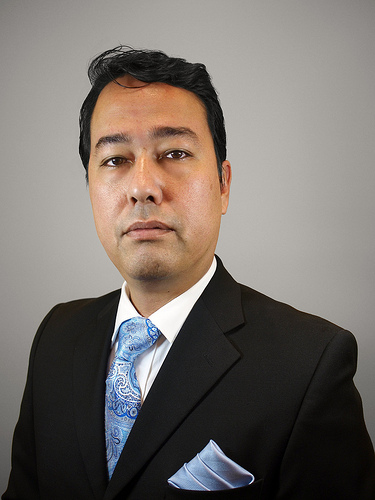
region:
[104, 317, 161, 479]
blue paisley neck tie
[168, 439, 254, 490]
pocket kerchief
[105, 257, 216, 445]
white collared shirt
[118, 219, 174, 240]
his mouth is closed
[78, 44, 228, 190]
He has short black hair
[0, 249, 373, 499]
the man is wearing a black suit jacket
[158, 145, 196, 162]
The man's eye is brown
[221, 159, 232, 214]
this is the man's ear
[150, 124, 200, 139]
The man's eyebrow is black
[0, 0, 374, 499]
the background is grey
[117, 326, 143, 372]
the tie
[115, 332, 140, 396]
the tie is blue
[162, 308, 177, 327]
a collar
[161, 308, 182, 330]
the collar is white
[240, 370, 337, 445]
a black suit the man is wearing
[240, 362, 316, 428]
the suit is black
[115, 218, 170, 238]
the mans lips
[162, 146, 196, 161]
left eye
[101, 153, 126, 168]
right eye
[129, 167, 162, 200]
the mans nose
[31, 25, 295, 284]
a man standing inside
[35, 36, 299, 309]
a man with black hair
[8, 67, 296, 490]
a man wearing a tie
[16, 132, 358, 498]
a man wearing a blue tie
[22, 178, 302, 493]
a man wearing a white shirt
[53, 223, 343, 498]
a man wearing a suit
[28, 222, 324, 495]
a man wearing a suit jacket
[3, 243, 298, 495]
a man wearing a tie and jacket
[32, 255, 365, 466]
a man wearing a black jacket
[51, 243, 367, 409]
a man wearing a black suit jacket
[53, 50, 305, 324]
Man posing for a portrait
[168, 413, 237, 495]
Pocket square in his pocket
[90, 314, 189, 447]
Man wearing a tie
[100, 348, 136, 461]
Pattern on the tie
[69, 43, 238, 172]
Man has dark hair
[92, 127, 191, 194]
Man has brown eyes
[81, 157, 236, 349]
Man recently shaved his face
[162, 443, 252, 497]
The pocket square is folded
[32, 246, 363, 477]
Man wearing a suit jacket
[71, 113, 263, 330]
Man is making a serious face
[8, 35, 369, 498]
man wears a suit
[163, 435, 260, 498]
a handkerchief in the pocket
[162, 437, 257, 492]
the handkerchief is color blue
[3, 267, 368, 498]
a suit color black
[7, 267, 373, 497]
a white shirt under a black suit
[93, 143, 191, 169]
eyes are brown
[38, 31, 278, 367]
man has black hair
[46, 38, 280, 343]
man has short hair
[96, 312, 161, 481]
a blue tie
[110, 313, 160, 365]
the knot of a tie